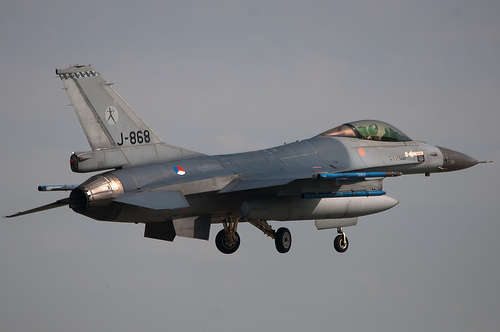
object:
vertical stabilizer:
[54, 62, 209, 174]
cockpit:
[319, 119, 413, 142]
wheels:
[213, 227, 242, 255]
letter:
[117, 132, 124, 146]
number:
[129, 131, 137, 145]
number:
[136, 130, 143, 143]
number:
[144, 129, 151, 143]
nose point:
[478, 159, 496, 164]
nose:
[433, 143, 497, 174]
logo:
[173, 165, 187, 176]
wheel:
[332, 233, 349, 254]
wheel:
[274, 226, 293, 254]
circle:
[173, 165, 186, 175]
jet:
[4, 63, 495, 255]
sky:
[0, 0, 500, 332]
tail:
[5, 62, 208, 225]